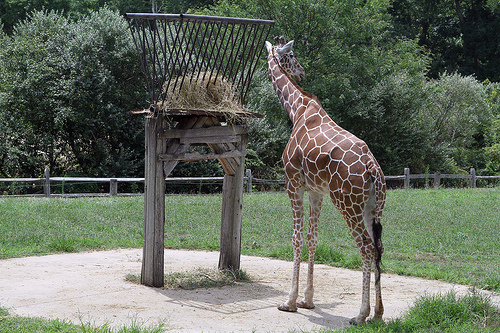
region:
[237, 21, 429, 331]
Giraffe standing inside the zoo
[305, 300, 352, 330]
Shadow of the giraffe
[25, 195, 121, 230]
Green color grass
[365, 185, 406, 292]
Tail with fringes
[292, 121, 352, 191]
Brown polygons on a cream color background of the giraffe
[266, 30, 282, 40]
Short knobbed horn of the giraffe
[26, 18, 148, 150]
Trees with leaves and branches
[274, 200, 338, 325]
Long legs of the giraffe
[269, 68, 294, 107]
Neck of the giraffe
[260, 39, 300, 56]
Ears of the giraffe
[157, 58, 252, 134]
hay in a feed troft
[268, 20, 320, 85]
a giraffe with its head turned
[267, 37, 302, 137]
a giraffe with a long neck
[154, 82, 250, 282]
a wood stand for a feed troft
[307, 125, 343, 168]
a pattern of spots on a giraffe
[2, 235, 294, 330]
a patch of sand in a field of grass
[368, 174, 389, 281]
a giraffes tail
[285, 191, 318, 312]
a giraffes long front legs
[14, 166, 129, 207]
a metal and wood fence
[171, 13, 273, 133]
a black iron basket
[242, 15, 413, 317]
this is a giraffe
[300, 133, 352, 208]
brown spots on the giraffe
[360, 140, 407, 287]
tail of the giraffe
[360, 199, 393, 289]
hair on giraffe tail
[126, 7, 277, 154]
this is a feeder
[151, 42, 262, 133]
hay in the feeder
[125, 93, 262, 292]
wooden posts for the feeder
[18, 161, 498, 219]
wooden fence in the background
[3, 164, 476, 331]
post on the concrete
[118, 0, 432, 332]
giraffe standing near feeder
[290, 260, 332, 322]
this is a leg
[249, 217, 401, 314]
there are four legs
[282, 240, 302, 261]
this is a knee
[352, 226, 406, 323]
this is a tail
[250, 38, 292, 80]
this is a head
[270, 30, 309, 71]
this is an ear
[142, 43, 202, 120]
this is a cage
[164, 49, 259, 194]
the cage is metal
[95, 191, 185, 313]
this is made of wood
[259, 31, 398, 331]
tall giraffe facing away in the field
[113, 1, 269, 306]
tall structure filled with hay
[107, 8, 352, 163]
hay for the giraffe to eat in feeder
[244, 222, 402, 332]
giraffe standing on the paved area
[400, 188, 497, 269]
lush green grass field behind giraffe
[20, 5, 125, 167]
tall green trees growing behind giraffe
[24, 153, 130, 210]
small wooden fence around giraffe habitat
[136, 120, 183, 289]
wood posts supporting the giraffe feeder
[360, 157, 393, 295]
tail with long brown hair on giraffe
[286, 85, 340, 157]
bony spine of giraffe can be seen